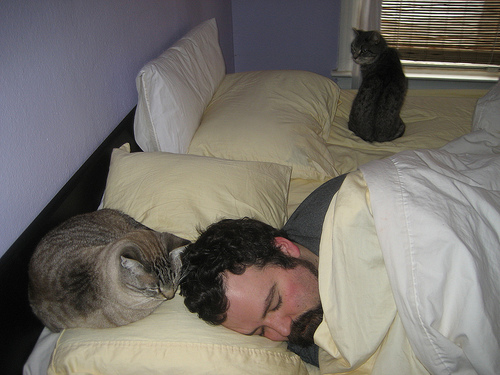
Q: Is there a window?
A: Yes, there is a window.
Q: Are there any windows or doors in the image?
A: Yes, there is a window.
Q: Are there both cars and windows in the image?
A: No, there is a window but no cars.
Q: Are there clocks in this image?
A: No, there are no clocks.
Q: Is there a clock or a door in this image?
A: No, there are no clocks or doors.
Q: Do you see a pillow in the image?
A: Yes, there is a pillow.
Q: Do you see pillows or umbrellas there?
A: Yes, there is a pillow.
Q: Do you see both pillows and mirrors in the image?
A: No, there is a pillow but no mirrors.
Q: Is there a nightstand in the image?
A: No, there are no nightstands.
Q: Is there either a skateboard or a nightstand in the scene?
A: No, there are no nightstands or skateboards.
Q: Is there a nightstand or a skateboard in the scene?
A: No, there are no nightstands or skateboards.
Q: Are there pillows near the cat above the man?
A: Yes, there is a pillow near the cat.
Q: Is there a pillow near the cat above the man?
A: Yes, there is a pillow near the cat.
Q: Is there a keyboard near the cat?
A: No, there is a pillow near the cat.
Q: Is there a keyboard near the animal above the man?
A: No, there is a pillow near the cat.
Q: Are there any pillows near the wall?
A: Yes, there is a pillow near the wall.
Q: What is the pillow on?
A: The pillow is on the bed.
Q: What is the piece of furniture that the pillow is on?
A: The piece of furniture is a bed.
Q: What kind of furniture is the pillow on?
A: The pillow is on the bed.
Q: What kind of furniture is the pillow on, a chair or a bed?
A: The pillow is on a bed.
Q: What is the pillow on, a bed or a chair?
A: The pillow is on a bed.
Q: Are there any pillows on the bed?
A: Yes, there is a pillow on the bed.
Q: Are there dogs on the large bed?
A: No, there is a pillow on the bed.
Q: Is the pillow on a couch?
A: No, the pillow is on a bed.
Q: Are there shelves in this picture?
A: No, there are no shelves.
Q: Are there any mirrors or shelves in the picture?
A: No, there are no shelves or mirrors.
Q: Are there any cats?
A: Yes, there is a cat.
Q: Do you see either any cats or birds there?
A: Yes, there is a cat.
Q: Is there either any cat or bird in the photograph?
A: Yes, there is a cat.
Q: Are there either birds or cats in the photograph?
A: Yes, there is a cat.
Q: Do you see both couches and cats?
A: No, there is a cat but no couches.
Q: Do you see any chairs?
A: No, there are no chairs.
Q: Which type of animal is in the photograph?
A: The animal is a cat.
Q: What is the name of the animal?
A: The animal is a cat.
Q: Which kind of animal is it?
A: The animal is a cat.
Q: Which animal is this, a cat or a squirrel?
A: This is a cat.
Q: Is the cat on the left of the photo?
A: Yes, the cat is on the left of the image.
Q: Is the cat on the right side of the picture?
A: No, the cat is on the left of the image.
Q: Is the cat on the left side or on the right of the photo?
A: The cat is on the left of the image.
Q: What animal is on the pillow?
A: The animal is a cat.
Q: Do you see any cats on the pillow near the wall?
A: Yes, there is a cat on the pillow.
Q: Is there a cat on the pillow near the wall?
A: Yes, there is a cat on the pillow.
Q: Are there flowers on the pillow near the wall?
A: No, there is a cat on the pillow.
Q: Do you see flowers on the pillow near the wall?
A: No, there is a cat on the pillow.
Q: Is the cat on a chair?
A: No, the cat is on the pillow.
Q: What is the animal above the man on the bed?
A: The animal is a cat.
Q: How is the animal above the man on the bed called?
A: The animal is a cat.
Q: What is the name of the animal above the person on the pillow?
A: The animal is a cat.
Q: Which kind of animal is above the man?
A: The animal is a cat.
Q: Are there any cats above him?
A: Yes, there is a cat above the man.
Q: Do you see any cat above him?
A: Yes, there is a cat above the man.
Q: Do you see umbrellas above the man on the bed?
A: No, there is a cat above the man.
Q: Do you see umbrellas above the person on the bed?
A: No, there is a cat above the man.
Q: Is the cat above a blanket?
A: No, the cat is above the man.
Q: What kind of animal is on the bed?
A: The animal is a cat.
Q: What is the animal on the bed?
A: The animal is a cat.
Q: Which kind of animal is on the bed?
A: The animal is a cat.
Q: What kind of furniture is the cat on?
A: The cat is on the bed.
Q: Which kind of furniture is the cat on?
A: The cat is on the bed.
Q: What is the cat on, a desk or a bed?
A: The cat is on a bed.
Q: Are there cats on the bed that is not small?
A: Yes, there is a cat on the bed.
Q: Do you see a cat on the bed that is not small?
A: Yes, there is a cat on the bed.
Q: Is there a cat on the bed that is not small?
A: Yes, there is a cat on the bed.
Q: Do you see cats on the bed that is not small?
A: Yes, there is a cat on the bed.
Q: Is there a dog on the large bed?
A: No, there is a cat on the bed.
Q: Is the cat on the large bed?
A: Yes, the cat is on the bed.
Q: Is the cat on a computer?
A: No, the cat is on the bed.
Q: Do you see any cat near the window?
A: Yes, there is a cat near the window.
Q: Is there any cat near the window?
A: Yes, there is a cat near the window.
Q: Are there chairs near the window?
A: No, there is a cat near the window.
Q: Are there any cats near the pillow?
A: Yes, there is a cat near the pillow.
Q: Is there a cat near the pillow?
A: Yes, there is a cat near the pillow.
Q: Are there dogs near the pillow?
A: No, there is a cat near the pillow.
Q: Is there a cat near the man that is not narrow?
A: Yes, there is a cat near the man.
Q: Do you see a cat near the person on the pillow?
A: Yes, there is a cat near the man.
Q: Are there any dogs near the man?
A: No, there is a cat near the man.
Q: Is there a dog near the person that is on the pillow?
A: No, there is a cat near the man.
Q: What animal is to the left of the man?
A: The animal is a cat.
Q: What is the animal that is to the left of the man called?
A: The animal is a cat.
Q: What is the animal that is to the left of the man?
A: The animal is a cat.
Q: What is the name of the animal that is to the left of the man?
A: The animal is a cat.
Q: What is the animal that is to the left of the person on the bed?
A: The animal is a cat.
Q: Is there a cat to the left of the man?
A: Yes, there is a cat to the left of the man.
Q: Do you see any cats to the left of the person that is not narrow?
A: Yes, there is a cat to the left of the man.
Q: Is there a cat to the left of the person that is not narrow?
A: Yes, there is a cat to the left of the man.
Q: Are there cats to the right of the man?
A: No, the cat is to the left of the man.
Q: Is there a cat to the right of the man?
A: No, the cat is to the left of the man.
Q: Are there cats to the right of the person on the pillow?
A: No, the cat is to the left of the man.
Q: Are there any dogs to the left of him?
A: No, there is a cat to the left of the man.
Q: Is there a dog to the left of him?
A: No, there is a cat to the left of the man.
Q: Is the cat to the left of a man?
A: Yes, the cat is to the left of a man.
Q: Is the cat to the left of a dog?
A: No, the cat is to the left of a man.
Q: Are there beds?
A: Yes, there is a bed.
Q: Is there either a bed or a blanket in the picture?
A: Yes, there is a bed.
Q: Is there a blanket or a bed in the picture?
A: Yes, there is a bed.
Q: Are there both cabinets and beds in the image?
A: No, there is a bed but no cabinets.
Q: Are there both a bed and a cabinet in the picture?
A: No, there is a bed but no cabinets.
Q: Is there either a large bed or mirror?
A: Yes, there is a large bed.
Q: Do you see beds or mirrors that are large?
A: Yes, the bed is large.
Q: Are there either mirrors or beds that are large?
A: Yes, the bed is large.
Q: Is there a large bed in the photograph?
A: Yes, there is a large bed.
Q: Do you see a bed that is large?
A: Yes, there is a bed that is large.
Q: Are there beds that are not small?
A: Yes, there is a large bed.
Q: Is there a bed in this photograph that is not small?
A: Yes, there is a large bed.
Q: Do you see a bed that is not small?
A: Yes, there is a large bed.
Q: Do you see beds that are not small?
A: Yes, there is a large bed.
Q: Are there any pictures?
A: No, there are no pictures.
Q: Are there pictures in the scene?
A: No, there are no pictures.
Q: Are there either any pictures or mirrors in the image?
A: No, there are no pictures or mirrors.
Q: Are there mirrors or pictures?
A: No, there are no pictures or mirrors.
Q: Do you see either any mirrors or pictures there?
A: No, there are no pictures or mirrors.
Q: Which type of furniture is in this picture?
A: The furniture is a bed.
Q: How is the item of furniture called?
A: The piece of furniture is a bed.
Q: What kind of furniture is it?
A: The piece of furniture is a bed.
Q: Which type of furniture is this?
A: This is a bed.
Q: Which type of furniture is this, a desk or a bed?
A: This is a bed.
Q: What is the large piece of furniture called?
A: The piece of furniture is a bed.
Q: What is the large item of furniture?
A: The piece of furniture is a bed.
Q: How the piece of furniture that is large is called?
A: The piece of furniture is a bed.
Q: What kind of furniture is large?
A: The furniture is a bed.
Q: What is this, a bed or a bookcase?
A: This is a bed.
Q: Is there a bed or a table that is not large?
A: No, there is a bed but it is large.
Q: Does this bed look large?
A: Yes, the bed is large.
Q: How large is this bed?
A: The bed is large.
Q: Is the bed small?
A: No, the bed is large.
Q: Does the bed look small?
A: No, the bed is large.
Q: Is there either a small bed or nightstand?
A: No, there is a bed but it is large.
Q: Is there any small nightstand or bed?
A: No, there is a bed but it is large.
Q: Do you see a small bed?
A: No, there is a bed but it is large.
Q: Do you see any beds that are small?
A: No, there is a bed but it is large.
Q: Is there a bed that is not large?
A: No, there is a bed but it is large.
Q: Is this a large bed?
A: Yes, this is a large bed.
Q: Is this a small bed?
A: No, this is a large bed.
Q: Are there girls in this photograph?
A: No, there are no girls.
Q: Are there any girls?
A: No, there are no girls.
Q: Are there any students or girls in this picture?
A: No, there are no girls or students.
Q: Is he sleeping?
A: Yes, the man is sleeping.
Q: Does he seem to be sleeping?
A: Yes, the man is sleeping.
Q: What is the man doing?
A: The man is sleeping.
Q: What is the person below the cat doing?
A: The man is sleeping.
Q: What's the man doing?
A: The man is sleeping.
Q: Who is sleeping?
A: The man is sleeping.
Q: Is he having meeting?
A: No, the man is sleeping.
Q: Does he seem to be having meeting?
A: No, the man is sleeping.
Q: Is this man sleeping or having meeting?
A: The man is sleeping.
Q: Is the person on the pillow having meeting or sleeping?
A: The man is sleeping.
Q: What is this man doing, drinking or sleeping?
A: The man is sleeping.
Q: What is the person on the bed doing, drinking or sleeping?
A: The man is sleeping.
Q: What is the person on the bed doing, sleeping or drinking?
A: The man is sleeping.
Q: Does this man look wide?
A: Yes, the man is wide.